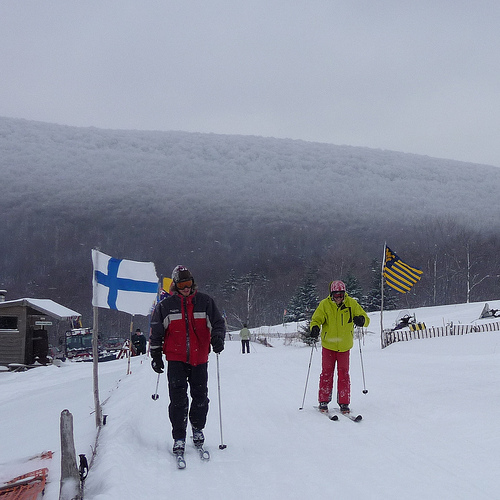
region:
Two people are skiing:
[142, 261, 375, 474]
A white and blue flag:
[83, 245, 164, 321]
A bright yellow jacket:
[303, 287, 371, 357]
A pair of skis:
[163, 422, 213, 473]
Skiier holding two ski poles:
[292, 276, 376, 416]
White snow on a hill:
[1, 292, 498, 496]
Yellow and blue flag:
[373, 235, 426, 296]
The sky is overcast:
[1, 2, 498, 173]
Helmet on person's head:
[323, 275, 351, 304]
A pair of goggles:
[168, 273, 196, 295]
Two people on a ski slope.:
[126, 229, 380, 482]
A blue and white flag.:
[83, 234, 159, 323]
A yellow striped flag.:
[377, 240, 421, 295]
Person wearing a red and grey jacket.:
[141, 260, 230, 369]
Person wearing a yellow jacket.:
[306, 283, 368, 358]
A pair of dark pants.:
[162, 352, 212, 439]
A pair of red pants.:
[312, 342, 360, 408]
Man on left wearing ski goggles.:
[154, 258, 206, 302]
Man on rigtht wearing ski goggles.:
[327, 277, 351, 301]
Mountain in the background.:
[7, 114, 487, 316]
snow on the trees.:
[230, 148, 297, 178]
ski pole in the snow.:
[217, 431, 229, 454]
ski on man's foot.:
[172, 453, 187, 472]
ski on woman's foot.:
[322, 411, 340, 423]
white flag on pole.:
[101, 255, 152, 310]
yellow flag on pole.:
[388, 254, 424, 295]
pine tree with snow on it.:
[289, 275, 315, 314]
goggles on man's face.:
[173, 273, 195, 291]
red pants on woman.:
[338, 363, 353, 408]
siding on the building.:
[5, 336, 17, 354]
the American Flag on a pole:
[367, 228, 424, 355]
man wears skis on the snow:
[292, 269, 379, 431]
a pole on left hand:
[347, 306, 384, 401]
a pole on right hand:
[295, 325, 319, 420]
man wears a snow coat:
[135, 253, 247, 477]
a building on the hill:
[2, 278, 94, 395]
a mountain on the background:
[5, 93, 479, 330]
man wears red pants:
[295, 271, 379, 418]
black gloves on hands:
[302, 309, 369, 353]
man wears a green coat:
[295, 272, 376, 373]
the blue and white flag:
[79, 241, 165, 312]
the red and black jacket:
[154, 278, 217, 366]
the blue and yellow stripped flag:
[376, 249, 418, 298]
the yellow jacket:
[315, 288, 371, 358]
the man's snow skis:
[165, 406, 235, 473]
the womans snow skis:
[307, 396, 376, 430]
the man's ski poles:
[139, 346, 264, 453]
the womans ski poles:
[293, 323, 383, 415]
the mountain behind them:
[17, 131, 485, 308]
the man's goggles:
[164, 271, 203, 291]